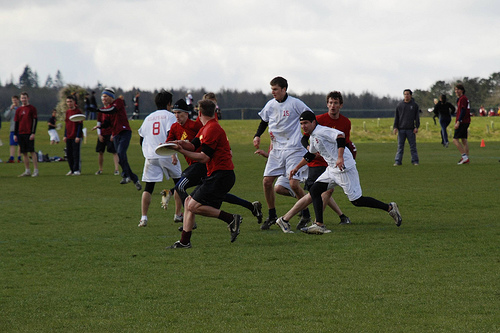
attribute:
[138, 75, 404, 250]
people — playing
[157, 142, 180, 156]
frisbee — white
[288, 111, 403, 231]
man — running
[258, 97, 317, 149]
shirt — white, blue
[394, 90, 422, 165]
man — standing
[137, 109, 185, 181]
uniform — white, red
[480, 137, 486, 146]
cone — orange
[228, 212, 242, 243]
shoe — black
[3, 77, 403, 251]
group — big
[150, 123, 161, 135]
number — 8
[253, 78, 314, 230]
boy — tall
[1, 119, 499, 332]
ground — green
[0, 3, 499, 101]
sky — cool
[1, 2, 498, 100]
cloud — beautiful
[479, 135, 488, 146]
object — red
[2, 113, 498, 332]
grass — manicured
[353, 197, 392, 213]
socks — black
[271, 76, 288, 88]
hair — brown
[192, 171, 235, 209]
shorts — black